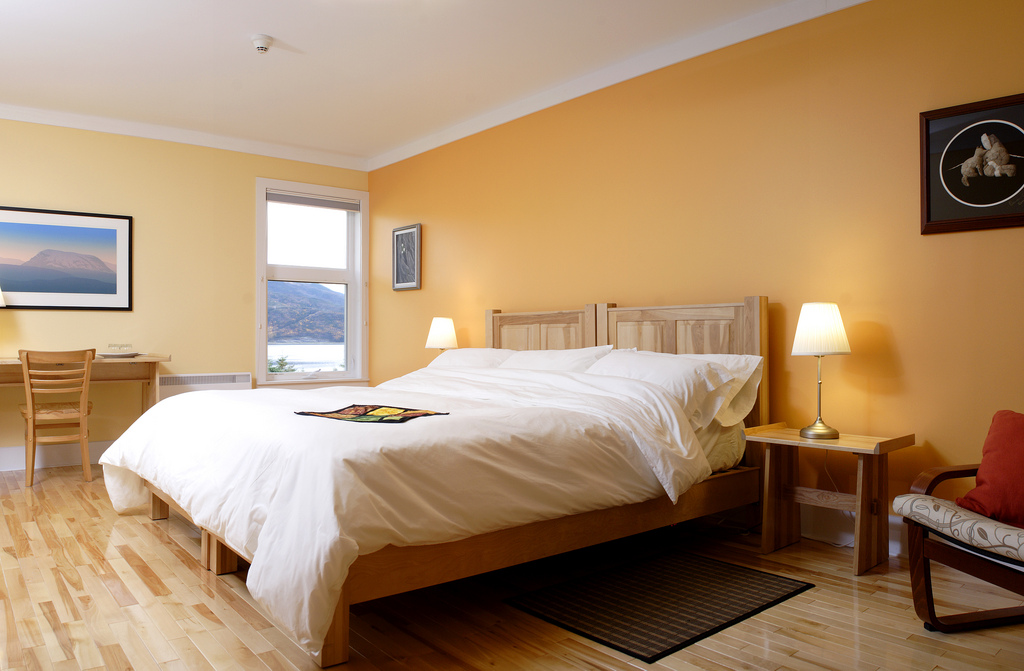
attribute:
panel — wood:
[600, 306, 681, 346]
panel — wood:
[619, 318, 741, 351]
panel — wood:
[612, 318, 663, 351]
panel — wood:
[695, 318, 737, 357]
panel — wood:
[635, 319, 659, 343]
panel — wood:
[620, 322, 639, 339]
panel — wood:
[541, 325, 567, 344]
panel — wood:
[677, 323, 701, 352]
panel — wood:
[538, 323, 552, 340]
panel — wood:
[516, 323, 535, 343]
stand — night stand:
[740, 401, 922, 579]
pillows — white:
[447, 326, 739, 421]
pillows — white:
[428, 313, 738, 431]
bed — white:
[141, 299, 759, 607]